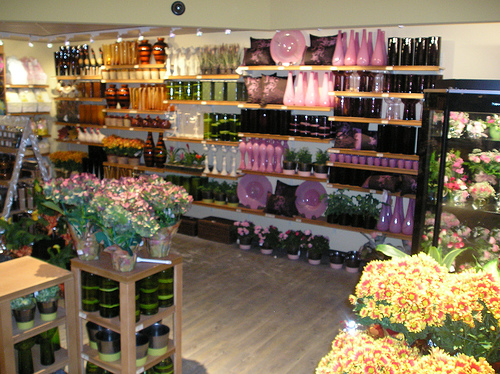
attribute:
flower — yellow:
[405, 318, 425, 333]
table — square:
[69, 243, 186, 372]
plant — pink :
[100, 182, 166, 269]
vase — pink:
[371, 28, 386, 68]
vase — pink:
[354, 25, 371, 68]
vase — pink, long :
[343, 26, 356, 64]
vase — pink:
[330, 26, 346, 67]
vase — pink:
[317, 70, 330, 109]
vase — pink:
[305, 68, 316, 107]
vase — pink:
[291, 67, 304, 108]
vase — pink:
[281, 68, 293, 107]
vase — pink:
[272, 138, 282, 173]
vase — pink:
[265, 139, 275, 171]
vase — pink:
[258, 137, 268, 169]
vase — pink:
[251, 138, 258, 169]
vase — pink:
[245, 135, 255, 169]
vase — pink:
[238, 135, 249, 170]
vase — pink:
[401, 194, 414, 231]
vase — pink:
[390, 189, 406, 234]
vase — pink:
[375, 191, 389, 231]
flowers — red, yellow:
[313, 241, 499, 372]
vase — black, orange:
[151, 38, 167, 62]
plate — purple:
[295, 171, 326, 223]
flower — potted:
[305, 232, 328, 266]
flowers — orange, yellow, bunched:
[335, 209, 490, 339]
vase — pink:
[332, 30, 345, 65]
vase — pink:
[258, 137, 278, 180]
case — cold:
[394, 124, 499, 318]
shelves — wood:
[85, 65, 411, 288]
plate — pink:
[272, 27, 303, 66]